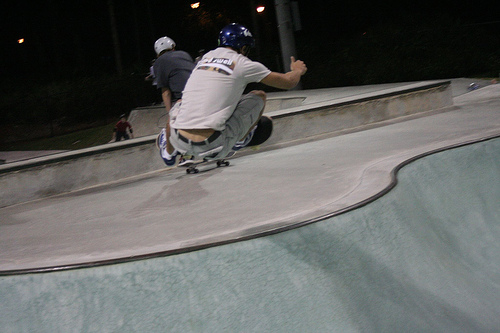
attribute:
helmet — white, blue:
[219, 21, 261, 47]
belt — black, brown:
[170, 123, 232, 149]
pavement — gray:
[194, 256, 299, 327]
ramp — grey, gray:
[213, 222, 401, 325]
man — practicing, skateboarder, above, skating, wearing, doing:
[153, 23, 289, 151]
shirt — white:
[193, 46, 245, 140]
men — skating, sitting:
[102, 111, 151, 153]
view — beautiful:
[55, 12, 138, 84]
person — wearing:
[153, 26, 313, 195]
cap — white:
[142, 24, 172, 60]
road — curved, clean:
[110, 174, 164, 224]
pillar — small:
[249, 1, 310, 37]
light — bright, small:
[255, 1, 283, 30]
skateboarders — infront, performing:
[138, 34, 272, 181]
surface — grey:
[288, 144, 378, 247]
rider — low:
[167, 140, 243, 185]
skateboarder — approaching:
[189, 34, 305, 151]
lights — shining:
[182, 3, 310, 23]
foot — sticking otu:
[158, 134, 191, 166]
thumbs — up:
[274, 43, 314, 73]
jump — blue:
[282, 245, 364, 295]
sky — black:
[59, 16, 138, 64]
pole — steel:
[100, 23, 153, 81]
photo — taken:
[20, 14, 441, 297]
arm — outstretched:
[257, 62, 306, 80]